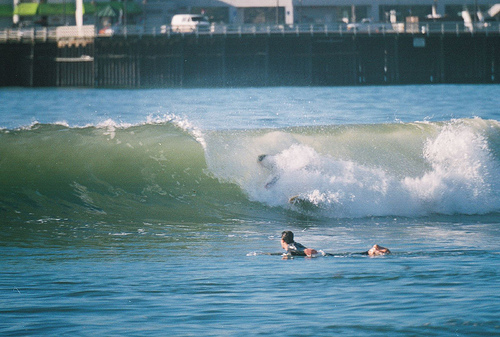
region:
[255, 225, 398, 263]
the man on the surfboard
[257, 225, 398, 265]
the man paddling in the water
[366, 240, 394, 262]
the feet in the water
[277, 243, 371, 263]
the wet suit on the man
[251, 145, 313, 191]
the surfer in the wave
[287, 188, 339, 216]
the board in the water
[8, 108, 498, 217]
the wave swallowing the surfer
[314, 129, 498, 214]
the water from the wave crashing down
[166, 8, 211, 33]
the white van on the docks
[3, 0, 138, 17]
the green umbrellas on the pier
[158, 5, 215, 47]
van on the boardwalkd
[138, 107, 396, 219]
waves crashing in the water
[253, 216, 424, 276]
person swimming in the water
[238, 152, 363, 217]
person swimming in the water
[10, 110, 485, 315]
A person is in the water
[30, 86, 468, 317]
A person is looking at a big wave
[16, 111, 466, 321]
The person is ready to catch the wave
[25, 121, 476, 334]
The person is getting very wet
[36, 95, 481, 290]
The person is close to a city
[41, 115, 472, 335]
The person is on their day off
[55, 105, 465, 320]
A person is on their vacation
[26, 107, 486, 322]
The person is doing some swimming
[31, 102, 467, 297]
A person is out in the daytime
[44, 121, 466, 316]
The person is enjoying their day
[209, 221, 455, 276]
this person is lying on his board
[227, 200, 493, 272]
he is paddling out on the water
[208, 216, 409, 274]
he is headed towards the wave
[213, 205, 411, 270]
the is lying on his board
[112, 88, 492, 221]
the wave is crashing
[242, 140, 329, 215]
there is a person in the wave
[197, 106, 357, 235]
the wave is crashing on the wave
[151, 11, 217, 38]
this is a white van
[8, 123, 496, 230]
the water is green here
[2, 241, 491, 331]
the water here is blue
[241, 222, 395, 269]
person in the water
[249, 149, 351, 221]
person on board in water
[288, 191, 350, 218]
board person surfs on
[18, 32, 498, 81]
fence behind the water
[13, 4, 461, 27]
buildings behind the fence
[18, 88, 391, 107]
flattened water near fence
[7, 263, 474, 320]
flattened water near person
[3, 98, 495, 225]
elevated water in middle of water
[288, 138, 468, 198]
white water area of water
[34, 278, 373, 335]
blue water of water area